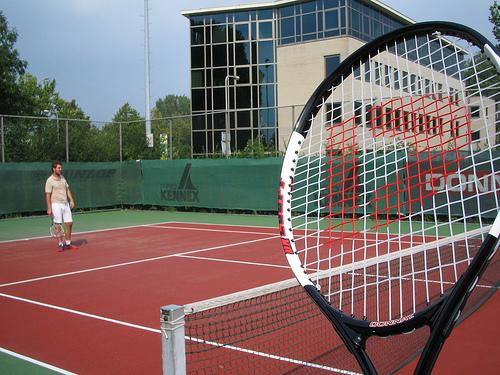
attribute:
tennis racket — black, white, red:
[281, 29, 499, 361]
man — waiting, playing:
[36, 156, 87, 253]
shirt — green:
[48, 182, 67, 201]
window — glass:
[213, 45, 228, 65]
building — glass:
[191, 8, 474, 142]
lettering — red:
[422, 169, 499, 198]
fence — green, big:
[145, 161, 271, 212]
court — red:
[5, 225, 281, 330]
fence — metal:
[10, 116, 174, 161]